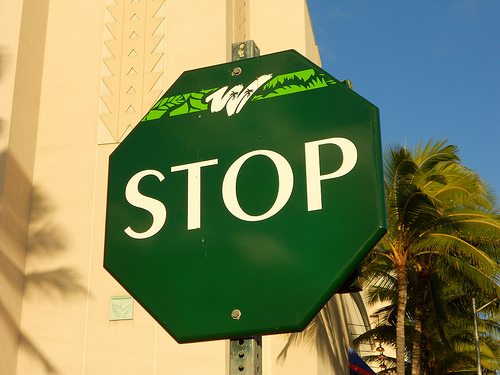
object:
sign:
[102, 48, 388, 345]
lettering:
[122, 168, 168, 240]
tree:
[363, 135, 500, 374]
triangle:
[347, 345, 377, 374]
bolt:
[230, 308, 241, 320]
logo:
[141, 67, 338, 123]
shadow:
[274, 280, 361, 375]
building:
[1, 0, 405, 374]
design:
[99, 1, 167, 145]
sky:
[307, 0, 497, 196]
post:
[229, 334, 265, 374]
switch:
[109, 296, 134, 321]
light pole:
[472, 297, 483, 374]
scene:
[1, 3, 500, 373]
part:
[366, 50, 417, 71]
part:
[236, 69, 240, 73]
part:
[232, 311, 235, 316]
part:
[147, 254, 190, 317]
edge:
[356, 290, 466, 324]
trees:
[359, 137, 449, 375]